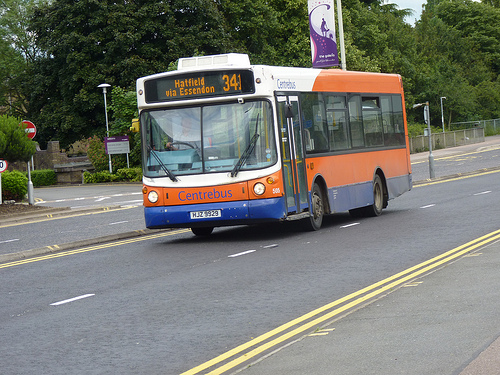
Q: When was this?
A: Daytime.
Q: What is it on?
A: A road.